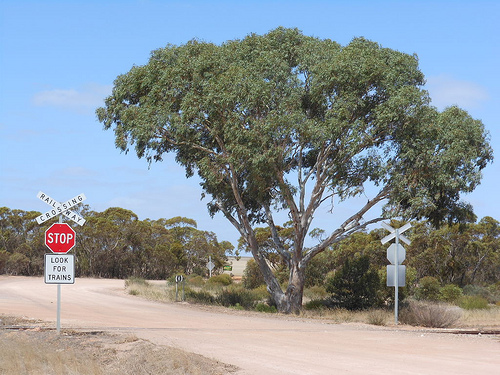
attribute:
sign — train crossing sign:
[32, 186, 89, 336]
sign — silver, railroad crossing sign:
[373, 224, 416, 333]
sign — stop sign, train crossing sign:
[41, 222, 83, 285]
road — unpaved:
[62, 313, 395, 357]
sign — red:
[19, 207, 103, 267]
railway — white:
[30, 188, 101, 330]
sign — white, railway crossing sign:
[28, 189, 90, 231]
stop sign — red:
[36, 218, 83, 255]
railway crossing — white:
[28, 188, 93, 339]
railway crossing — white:
[30, 185, 414, 341]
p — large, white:
[65, 232, 72, 244]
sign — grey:
[375, 211, 415, 246]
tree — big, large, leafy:
[92, 25, 499, 312]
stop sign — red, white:
[43, 220, 78, 253]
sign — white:
[34, 192, 86, 227]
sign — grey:
[373, 220, 413, 322]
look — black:
[46, 252, 69, 267]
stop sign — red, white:
[48, 220, 76, 254]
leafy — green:
[98, 25, 495, 224]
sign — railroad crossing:
[34, 192, 85, 223]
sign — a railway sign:
[174, 273, 184, 283]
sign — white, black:
[43, 252, 75, 287]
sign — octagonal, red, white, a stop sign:
[34, 217, 75, 253]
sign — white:
[29, 188, 89, 226]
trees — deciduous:
[89, 20, 488, 314]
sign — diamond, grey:
[207, 262, 216, 272]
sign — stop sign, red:
[25, 206, 93, 296]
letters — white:
[46, 233, 71, 243]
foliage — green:
[96, 24, 493, 239]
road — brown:
[2, 266, 484, 373]